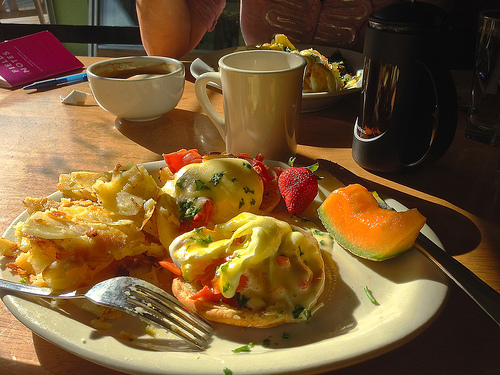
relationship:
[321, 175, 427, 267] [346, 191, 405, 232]
cantaloupe has bite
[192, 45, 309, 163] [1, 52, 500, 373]
mug on table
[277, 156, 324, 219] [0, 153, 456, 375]
strawberry on plate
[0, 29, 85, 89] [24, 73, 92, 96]
book beside pen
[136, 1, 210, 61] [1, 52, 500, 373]
elbow on table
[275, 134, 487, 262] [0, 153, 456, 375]
shadow near plate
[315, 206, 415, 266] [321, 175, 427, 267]
rind under cantaloupe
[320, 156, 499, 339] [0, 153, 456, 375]
knife on plate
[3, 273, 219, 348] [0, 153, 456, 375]
fork on plate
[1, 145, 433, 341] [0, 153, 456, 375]
breakfast on plate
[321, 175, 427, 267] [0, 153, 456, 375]
cantaloupe on plate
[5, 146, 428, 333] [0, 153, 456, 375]
food on plate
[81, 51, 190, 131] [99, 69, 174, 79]
cup has coffee